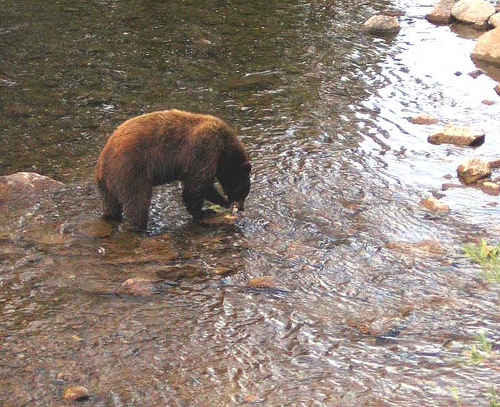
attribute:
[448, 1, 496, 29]
rock — large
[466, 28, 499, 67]
rock — large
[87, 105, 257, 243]
bear — drinking, fishing, brown, large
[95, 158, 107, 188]
tail — short, small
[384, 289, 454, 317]
spot — brown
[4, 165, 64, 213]
rock — large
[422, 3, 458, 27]
rock — large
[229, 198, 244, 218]
mouth — opened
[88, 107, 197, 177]
hair — dry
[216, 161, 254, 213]
head — brown